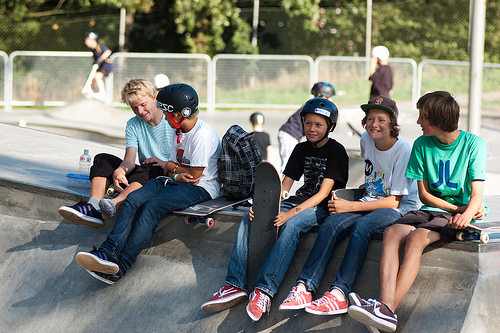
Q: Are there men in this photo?
A: No, there are no men.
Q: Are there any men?
A: No, there are no men.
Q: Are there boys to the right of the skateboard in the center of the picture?
A: Yes, there is a boy to the right of the skateboard.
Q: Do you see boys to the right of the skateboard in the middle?
A: Yes, there is a boy to the right of the skateboard.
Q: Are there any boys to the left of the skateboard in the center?
A: No, the boy is to the right of the skateboard.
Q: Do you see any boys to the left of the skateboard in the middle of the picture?
A: No, the boy is to the right of the skateboard.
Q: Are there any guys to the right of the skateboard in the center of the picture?
A: No, there is a boy to the right of the skateboard.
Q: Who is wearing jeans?
A: The boy is wearing jeans.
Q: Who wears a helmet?
A: The boy wears a helmet.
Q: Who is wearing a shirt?
A: The boy is wearing a shirt.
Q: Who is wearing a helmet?
A: The boy is wearing a helmet.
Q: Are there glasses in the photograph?
A: No, there are no glasses.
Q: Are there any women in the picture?
A: No, there are no women.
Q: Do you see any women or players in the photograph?
A: No, there are no women or players.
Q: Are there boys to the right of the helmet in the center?
A: Yes, there is a boy to the right of the helmet.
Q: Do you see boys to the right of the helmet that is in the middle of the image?
A: Yes, there is a boy to the right of the helmet.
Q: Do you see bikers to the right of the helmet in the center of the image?
A: No, there is a boy to the right of the helmet.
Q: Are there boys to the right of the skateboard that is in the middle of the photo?
A: Yes, there is a boy to the right of the skateboard.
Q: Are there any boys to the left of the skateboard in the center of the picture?
A: No, the boy is to the right of the skateboard.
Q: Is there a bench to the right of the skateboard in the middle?
A: No, there is a boy to the right of the skateboard.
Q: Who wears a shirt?
A: The boy wears a shirt.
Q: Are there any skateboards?
A: Yes, there is a skateboard.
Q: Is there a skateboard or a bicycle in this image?
A: Yes, there is a skateboard.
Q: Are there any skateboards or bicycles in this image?
A: Yes, there is a skateboard.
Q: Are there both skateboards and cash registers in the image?
A: No, there is a skateboard but no cash registers.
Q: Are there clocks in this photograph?
A: No, there are no clocks.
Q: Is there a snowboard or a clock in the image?
A: No, there are no clocks or snowboards.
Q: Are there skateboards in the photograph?
A: Yes, there is a skateboard.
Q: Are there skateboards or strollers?
A: Yes, there is a skateboard.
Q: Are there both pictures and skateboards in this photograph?
A: No, there is a skateboard but no pictures.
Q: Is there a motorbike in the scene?
A: No, there are no motorcycles.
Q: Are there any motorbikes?
A: No, there are no motorbikes.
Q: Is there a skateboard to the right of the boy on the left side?
A: Yes, there is a skateboard to the right of the boy.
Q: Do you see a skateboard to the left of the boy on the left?
A: No, the skateboard is to the right of the boy.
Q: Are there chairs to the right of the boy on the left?
A: No, there is a skateboard to the right of the boy.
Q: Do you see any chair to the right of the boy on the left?
A: No, there is a skateboard to the right of the boy.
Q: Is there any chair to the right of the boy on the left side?
A: No, there is a skateboard to the right of the boy.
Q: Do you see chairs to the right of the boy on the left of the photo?
A: No, there is a skateboard to the right of the boy.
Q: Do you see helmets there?
A: Yes, there is a helmet.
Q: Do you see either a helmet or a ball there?
A: Yes, there is a helmet.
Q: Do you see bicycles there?
A: No, there are no bicycles.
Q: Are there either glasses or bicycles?
A: No, there are no bicycles or glasses.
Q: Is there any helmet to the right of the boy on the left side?
A: Yes, there is a helmet to the right of the boy.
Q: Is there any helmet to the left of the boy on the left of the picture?
A: No, the helmet is to the right of the boy.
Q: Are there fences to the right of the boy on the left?
A: No, there is a helmet to the right of the boy.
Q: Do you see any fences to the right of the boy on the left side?
A: No, there is a helmet to the right of the boy.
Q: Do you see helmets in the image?
A: Yes, there is a helmet.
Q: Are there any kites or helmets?
A: Yes, there is a helmet.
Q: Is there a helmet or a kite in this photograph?
A: Yes, there is a helmet.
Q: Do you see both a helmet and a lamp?
A: No, there is a helmet but no lamps.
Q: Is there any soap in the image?
A: No, there are no soaps.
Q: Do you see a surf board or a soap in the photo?
A: No, there are no soaps or surfboards.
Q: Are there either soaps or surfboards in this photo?
A: No, there are no soaps or surfboards.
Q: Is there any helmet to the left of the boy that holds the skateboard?
A: Yes, there is a helmet to the left of the boy.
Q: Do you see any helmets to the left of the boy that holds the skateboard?
A: Yes, there is a helmet to the left of the boy.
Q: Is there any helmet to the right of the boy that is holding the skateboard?
A: No, the helmet is to the left of the boy.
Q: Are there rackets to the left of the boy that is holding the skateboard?
A: No, there is a helmet to the left of the boy.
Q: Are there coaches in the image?
A: No, there are no coaches.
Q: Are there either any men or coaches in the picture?
A: No, there are no coaches or men.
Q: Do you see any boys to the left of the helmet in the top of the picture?
A: Yes, there is a boy to the left of the helmet.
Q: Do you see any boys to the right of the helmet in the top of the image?
A: No, the boy is to the left of the helmet.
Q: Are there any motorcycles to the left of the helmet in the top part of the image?
A: No, there is a boy to the left of the helmet.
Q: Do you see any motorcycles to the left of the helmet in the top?
A: No, there is a boy to the left of the helmet.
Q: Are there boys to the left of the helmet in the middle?
A: Yes, there is a boy to the left of the helmet.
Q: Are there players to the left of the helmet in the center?
A: No, there is a boy to the left of the helmet.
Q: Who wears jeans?
A: The boy wears jeans.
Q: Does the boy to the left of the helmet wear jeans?
A: Yes, the boy wears jeans.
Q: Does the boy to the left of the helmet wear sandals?
A: No, the boy wears jeans.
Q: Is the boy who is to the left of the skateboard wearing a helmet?
A: Yes, the boy is wearing a helmet.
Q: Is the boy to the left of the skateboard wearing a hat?
A: No, the boy is wearing a helmet.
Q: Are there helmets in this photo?
A: Yes, there is a helmet.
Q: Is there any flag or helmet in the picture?
A: Yes, there is a helmet.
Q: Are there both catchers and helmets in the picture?
A: No, there is a helmet but no catchers.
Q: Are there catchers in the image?
A: No, there are no catchers.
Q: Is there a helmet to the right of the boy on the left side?
A: Yes, there is a helmet to the right of the boy.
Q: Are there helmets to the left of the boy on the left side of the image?
A: No, the helmet is to the right of the boy.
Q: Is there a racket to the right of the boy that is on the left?
A: No, there is a helmet to the right of the boy.